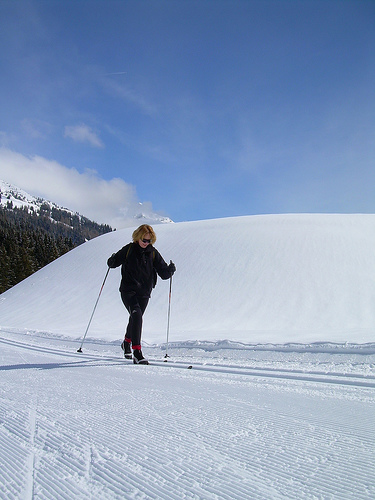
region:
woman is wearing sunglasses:
[128, 223, 158, 270]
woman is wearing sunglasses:
[125, 216, 158, 254]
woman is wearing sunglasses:
[131, 221, 156, 255]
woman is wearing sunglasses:
[129, 211, 159, 254]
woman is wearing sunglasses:
[126, 218, 171, 254]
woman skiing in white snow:
[90, 198, 182, 369]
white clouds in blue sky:
[205, 110, 251, 144]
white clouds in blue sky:
[67, 160, 106, 193]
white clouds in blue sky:
[195, 13, 257, 75]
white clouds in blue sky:
[115, 119, 169, 166]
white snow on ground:
[208, 391, 243, 421]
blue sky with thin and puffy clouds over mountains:
[6, 6, 371, 387]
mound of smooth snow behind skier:
[4, 211, 370, 372]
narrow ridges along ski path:
[7, 345, 368, 496]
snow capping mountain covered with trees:
[2, 170, 115, 299]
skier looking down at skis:
[77, 223, 195, 373]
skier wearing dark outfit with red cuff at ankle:
[105, 222, 176, 369]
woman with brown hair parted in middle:
[130, 222, 156, 249]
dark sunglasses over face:
[135, 232, 153, 249]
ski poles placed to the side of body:
[74, 249, 177, 367]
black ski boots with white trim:
[116, 336, 150, 367]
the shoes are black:
[114, 332, 159, 374]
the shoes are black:
[107, 330, 160, 366]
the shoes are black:
[115, 331, 164, 379]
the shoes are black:
[109, 328, 152, 374]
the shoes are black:
[114, 330, 150, 369]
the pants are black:
[112, 287, 153, 358]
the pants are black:
[109, 283, 154, 349]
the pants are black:
[109, 282, 147, 353]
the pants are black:
[102, 278, 145, 350]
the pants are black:
[109, 279, 152, 351]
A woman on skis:
[102, 224, 187, 363]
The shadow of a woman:
[0, 359, 136, 370]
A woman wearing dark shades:
[139, 236, 154, 244]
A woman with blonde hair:
[133, 224, 155, 243]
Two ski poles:
[77, 251, 172, 358]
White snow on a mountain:
[0, 178, 82, 214]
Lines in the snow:
[1, 342, 373, 498]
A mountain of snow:
[1, 212, 374, 343]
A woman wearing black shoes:
[119, 340, 147, 363]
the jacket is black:
[111, 240, 162, 302]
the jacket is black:
[107, 242, 172, 303]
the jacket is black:
[110, 234, 160, 305]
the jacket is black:
[108, 245, 170, 320]